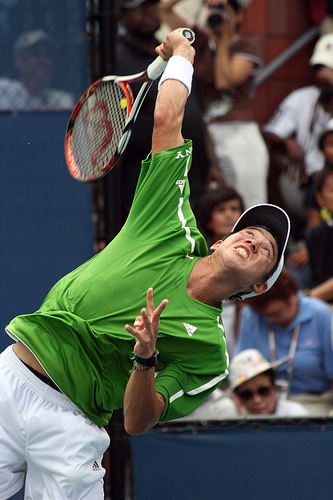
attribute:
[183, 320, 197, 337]
logo — adidas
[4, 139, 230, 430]
shirt — green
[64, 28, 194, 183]
raquet — wilson, multi-colored, wilsons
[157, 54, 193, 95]
armband — white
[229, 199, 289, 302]
hat — white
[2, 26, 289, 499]
player — playing, reaching, competing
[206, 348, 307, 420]
woman — watching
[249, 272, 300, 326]
head — down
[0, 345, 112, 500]
shorts — white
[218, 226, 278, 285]
face — straining